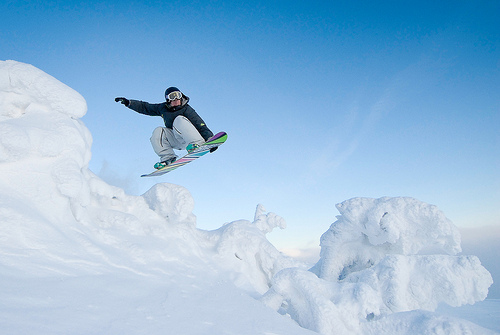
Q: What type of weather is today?
A: It is clear.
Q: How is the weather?
A: It is clear.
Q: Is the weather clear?
A: Yes, it is clear.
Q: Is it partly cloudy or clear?
A: It is clear.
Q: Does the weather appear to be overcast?
A: No, it is clear.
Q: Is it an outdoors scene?
A: Yes, it is outdoors.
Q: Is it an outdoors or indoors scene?
A: It is outdoors.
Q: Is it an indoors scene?
A: No, it is outdoors.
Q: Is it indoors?
A: No, it is outdoors.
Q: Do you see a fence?
A: No, there are no fences.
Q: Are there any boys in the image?
A: No, there are no boys.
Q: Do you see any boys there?
A: No, there are no boys.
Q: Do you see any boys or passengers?
A: No, there are no boys or passengers.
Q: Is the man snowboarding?
A: Yes, the man is snowboarding.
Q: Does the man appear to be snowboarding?
A: Yes, the man is snowboarding.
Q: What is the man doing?
A: The man is snowboarding.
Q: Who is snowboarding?
A: The man is snowboarding.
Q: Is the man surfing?
A: No, the man is snowboarding.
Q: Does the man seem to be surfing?
A: No, the man is snowboarding.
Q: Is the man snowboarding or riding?
A: The man is snowboarding.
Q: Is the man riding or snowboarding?
A: The man is snowboarding.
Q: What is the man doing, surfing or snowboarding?
A: The man is snowboarding.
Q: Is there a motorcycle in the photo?
A: No, there are no motorcycles.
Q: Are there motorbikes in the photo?
A: No, there are no motorbikes.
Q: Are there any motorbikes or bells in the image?
A: No, there are no motorbikes or bells.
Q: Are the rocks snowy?
A: Yes, the rocks are snowy.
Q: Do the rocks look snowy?
A: Yes, the rocks are snowy.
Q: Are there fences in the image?
A: No, there are no fences.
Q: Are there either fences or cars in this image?
A: No, there are no fences or cars.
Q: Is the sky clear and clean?
A: Yes, the sky is clear and clean.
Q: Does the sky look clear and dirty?
A: No, the sky is clear but clean.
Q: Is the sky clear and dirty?
A: No, the sky is clear but clean.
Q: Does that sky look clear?
A: Yes, the sky is clear.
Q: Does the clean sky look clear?
A: Yes, the sky is clear.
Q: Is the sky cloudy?
A: No, the sky is clear.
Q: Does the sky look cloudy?
A: No, the sky is clear.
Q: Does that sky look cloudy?
A: No, the sky is clear.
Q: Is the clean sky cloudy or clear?
A: The sky is clear.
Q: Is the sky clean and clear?
A: Yes, the sky is clean and clear.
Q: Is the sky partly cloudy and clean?
A: No, the sky is clean but clear.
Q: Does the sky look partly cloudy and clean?
A: No, the sky is clean but clear.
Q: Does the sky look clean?
A: Yes, the sky is clean.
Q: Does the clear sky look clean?
A: Yes, the sky is clean.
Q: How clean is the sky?
A: The sky is clean.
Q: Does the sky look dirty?
A: No, the sky is clean.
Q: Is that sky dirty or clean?
A: The sky is clean.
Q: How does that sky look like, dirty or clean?
A: The sky is clean.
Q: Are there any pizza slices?
A: No, there are no pizza slices.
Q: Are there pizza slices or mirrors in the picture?
A: No, there are no pizza slices or mirrors.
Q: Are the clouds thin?
A: Yes, the clouds are thin.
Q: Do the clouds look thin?
A: Yes, the clouds are thin.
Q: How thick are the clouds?
A: The clouds are thin.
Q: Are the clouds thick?
A: No, the clouds are thin.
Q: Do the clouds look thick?
A: No, the clouds are thin.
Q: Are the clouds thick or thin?
A: The clouds are thin.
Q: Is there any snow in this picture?
A: Yes, there is snow.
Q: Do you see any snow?
A: Yes, there is snow.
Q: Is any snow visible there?
A: Yes, there is snow.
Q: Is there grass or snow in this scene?
A: Yes, there is snow.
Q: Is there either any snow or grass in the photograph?
A: Yes, there is snow.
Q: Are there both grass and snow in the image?
A: No, there is snow but no grass.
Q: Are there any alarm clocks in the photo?
A: No, there are no alarm clocks.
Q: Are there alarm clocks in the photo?
A: No, there are no alarm clocks.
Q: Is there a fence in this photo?
A: No, there are no fences.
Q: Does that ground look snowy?
A: Yes, the ground is snowy.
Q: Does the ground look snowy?
A: Yes, the ground is snowy.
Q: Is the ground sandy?
A: No, the ground is snowy.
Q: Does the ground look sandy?
A: No, the ground is snowy.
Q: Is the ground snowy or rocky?
A: The ground is snowy.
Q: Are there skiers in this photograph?
A: No, there are no skiers.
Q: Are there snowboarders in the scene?
A: Yes, there is a snowboarder.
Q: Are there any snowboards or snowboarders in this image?
A: Yes, there is a snowboarder.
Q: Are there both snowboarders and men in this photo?
A: Yes, there are both a snowboarder and a man.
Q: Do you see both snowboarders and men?
A: Yes, there are both a snowboarder and a man.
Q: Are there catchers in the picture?
A: No, there are no catchers.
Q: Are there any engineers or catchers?
A: No, there are no catchers or engineers.